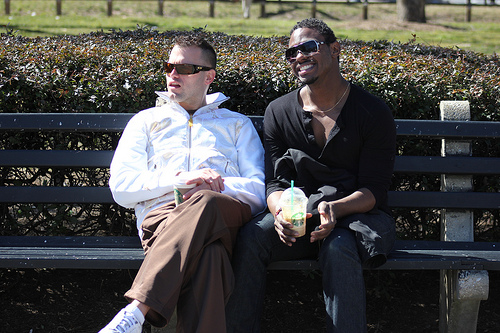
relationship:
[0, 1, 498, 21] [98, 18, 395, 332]
walking path for people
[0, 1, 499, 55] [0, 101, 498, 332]
grassy area behind bench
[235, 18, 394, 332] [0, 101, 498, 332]
people sitting on bench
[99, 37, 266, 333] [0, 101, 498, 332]
person sitting on bench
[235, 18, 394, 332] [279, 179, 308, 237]
people holding container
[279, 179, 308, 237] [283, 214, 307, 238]
container has beverage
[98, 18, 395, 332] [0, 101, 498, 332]
people sitting on bench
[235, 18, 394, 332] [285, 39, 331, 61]
people has on sunglasses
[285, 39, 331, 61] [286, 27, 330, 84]
sunglasses are on face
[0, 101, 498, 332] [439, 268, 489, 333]
bench has a stone leg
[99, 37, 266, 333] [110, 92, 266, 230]
person wearing jacket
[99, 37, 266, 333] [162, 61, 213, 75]
person wearing sunglasses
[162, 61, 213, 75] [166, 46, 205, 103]
sunglasses are on face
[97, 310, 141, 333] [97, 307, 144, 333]
shoe on foot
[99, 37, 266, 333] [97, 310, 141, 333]
person wearing shoe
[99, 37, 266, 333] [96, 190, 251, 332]
person has legs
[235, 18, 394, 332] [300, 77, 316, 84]
people has a goatee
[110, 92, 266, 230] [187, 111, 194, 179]
jacket has zipper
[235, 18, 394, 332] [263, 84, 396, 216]
people wearing shirt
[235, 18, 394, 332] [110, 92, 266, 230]
people holding jacket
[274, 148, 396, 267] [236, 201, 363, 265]
jacket in lap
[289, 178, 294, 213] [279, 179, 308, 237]
straw on a container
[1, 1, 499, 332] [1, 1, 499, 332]
scene of outside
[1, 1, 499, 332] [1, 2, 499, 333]
image taken during day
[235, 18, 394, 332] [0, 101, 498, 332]
people on bench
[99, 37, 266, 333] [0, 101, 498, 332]
person on bench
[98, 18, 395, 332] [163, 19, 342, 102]
people looking same way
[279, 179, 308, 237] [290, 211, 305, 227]
container from starbucks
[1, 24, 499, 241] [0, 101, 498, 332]
hedges are behind bench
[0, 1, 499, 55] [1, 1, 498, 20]
field in distance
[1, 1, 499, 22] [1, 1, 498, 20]
fence in distance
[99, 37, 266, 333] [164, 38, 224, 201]
person has light skin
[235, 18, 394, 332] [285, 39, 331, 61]
people has sunglasses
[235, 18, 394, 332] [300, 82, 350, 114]
people wears a necklace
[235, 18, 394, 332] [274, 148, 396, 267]
people has a jacket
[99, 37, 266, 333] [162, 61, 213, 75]
person has on sunglasses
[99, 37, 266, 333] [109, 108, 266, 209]
person has crossed arms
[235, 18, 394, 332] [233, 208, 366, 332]
people wearing pants